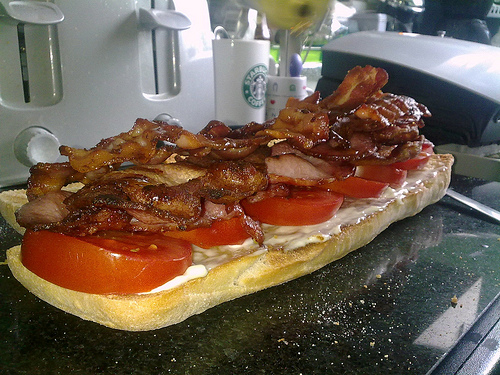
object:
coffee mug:
[210, 38, 268, 127]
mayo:
[140, 167, 442, 295]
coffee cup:
[266, 74, 309, 121]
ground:
[373, 163, 398, 185]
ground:
[426, 130, 456, 177]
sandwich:
[0, 65, 454, 331]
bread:
[0, 154, 454, 332]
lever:
[0, 0, 64, 24]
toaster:
[1, 0, 215, 188]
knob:
[13, 125, 61, 167]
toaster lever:
[137, 0, 192, 102]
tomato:
[19, 142, 452, 295]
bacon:
[14, 65, 431, 236]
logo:
[243, 66, 267, 109]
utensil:
[447, 187, 492, 218]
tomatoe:
[18, 228, 194, 297]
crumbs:
[154, 267, 496, 374]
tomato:
[164, 218, 251, 248]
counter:
[0, 171, 500, 372]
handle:
[141, 3, 192, 31]